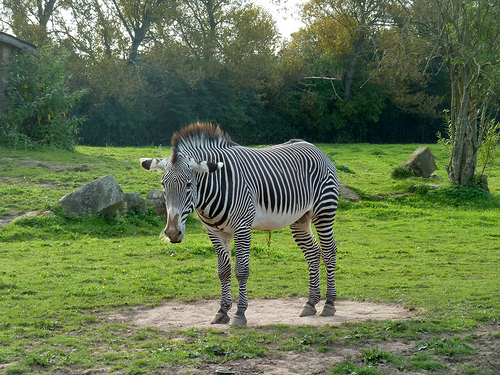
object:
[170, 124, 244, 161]
main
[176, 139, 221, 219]
neck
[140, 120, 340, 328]
zebra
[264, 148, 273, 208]
stripes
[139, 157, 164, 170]
ear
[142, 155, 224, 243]
head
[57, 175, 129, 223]
stone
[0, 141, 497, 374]
ground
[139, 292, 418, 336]
dirt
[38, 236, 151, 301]
grass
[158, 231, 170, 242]
whiskers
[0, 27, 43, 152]
building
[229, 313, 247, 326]
hooves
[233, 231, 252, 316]
legs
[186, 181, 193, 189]
eye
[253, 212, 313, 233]
belly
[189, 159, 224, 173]
ear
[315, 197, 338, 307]
legs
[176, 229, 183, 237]
nose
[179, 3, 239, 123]
tree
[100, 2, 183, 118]
tree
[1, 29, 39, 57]
roof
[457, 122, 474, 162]
bark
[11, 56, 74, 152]
bush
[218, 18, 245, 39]
branches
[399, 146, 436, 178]
rock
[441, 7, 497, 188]
tree